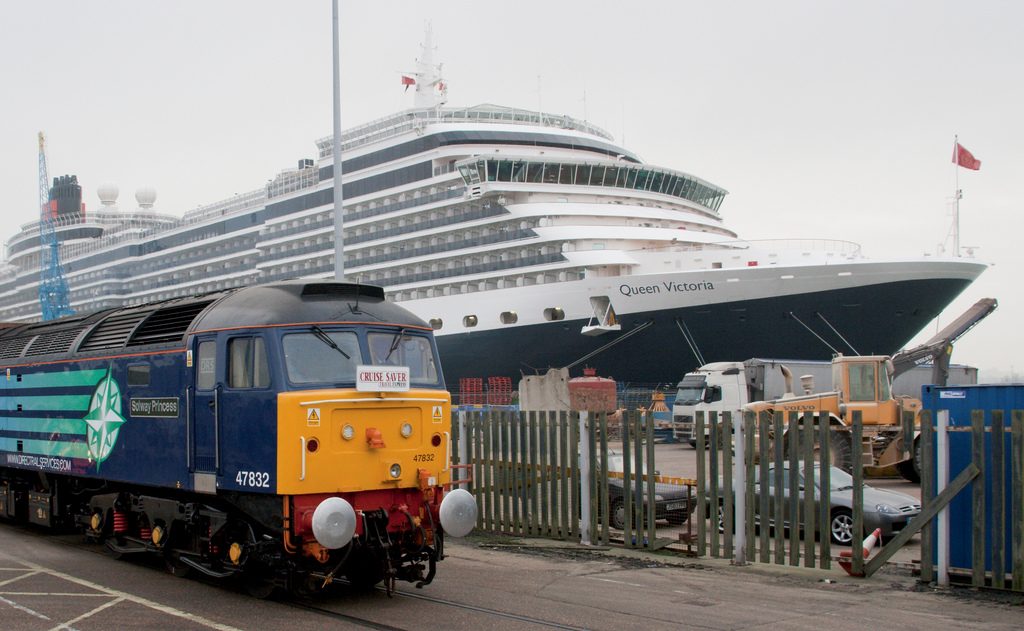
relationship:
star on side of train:
[65, 359, 136, 490] [2, 277, 461, 612]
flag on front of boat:
[931, 122, 985, 200] [0, 24, 988, 357]